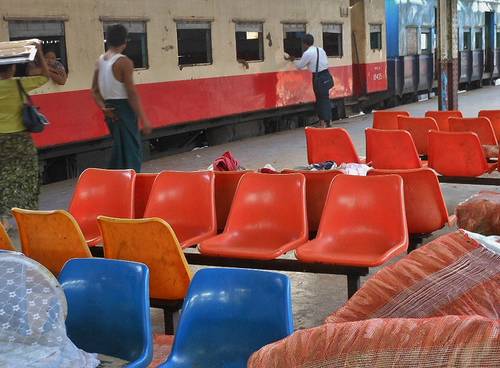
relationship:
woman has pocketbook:
[293, 32, 338, 127] [313, 44, 334, 96]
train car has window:
[0, 0, 389, 150] [7, 20, 71, 80]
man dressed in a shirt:
[291, 32, 336, 129] [294, 44, 328, 72]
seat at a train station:
[97, 214, 193, 300] [0, 0, 500, 368]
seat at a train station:
[11, 207, 93, 275] [0, 0, 500, 368]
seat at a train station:
[1, 222, 17, 251] [0, 0, 500, 368]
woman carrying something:
[1, 44, 50, 242] [0, 39, 45, 64]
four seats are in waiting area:
[68, 167, 414, 266] [1, 111, 498, 366]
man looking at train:
[94, 23, 153, 171] [2, 1, 499, 187]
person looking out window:
[23, 48, 68, 87] [7, 20, 71, 80]